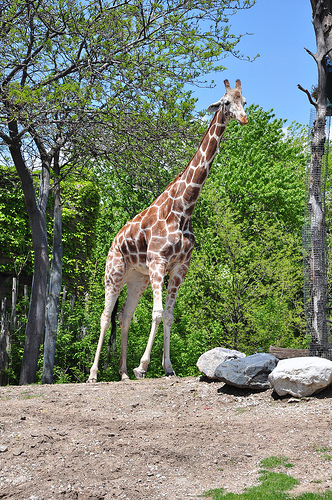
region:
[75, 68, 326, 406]
a giraffe near three stones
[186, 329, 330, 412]
three stones on the ground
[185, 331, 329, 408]
a black stone in the middle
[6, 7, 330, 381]
trees behind a giraffe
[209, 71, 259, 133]
head of giraffe is thin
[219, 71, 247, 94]
horns on head of giraffe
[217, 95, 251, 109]
eyes of giraffe are black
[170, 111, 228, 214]
long neck of giraffe has dark brown spots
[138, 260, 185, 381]
front legs of giraffe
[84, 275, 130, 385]
back legs of giraffe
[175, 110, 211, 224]
giraffe's neck is long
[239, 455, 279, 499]
green patches of grass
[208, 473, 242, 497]
green patches of grass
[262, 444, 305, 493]
green patches of grass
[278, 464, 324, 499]
green patches of grass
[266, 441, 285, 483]
green patches of grass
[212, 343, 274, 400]
the rock is gray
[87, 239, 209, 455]
giraffe's legs are long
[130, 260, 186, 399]
giraffe's legs are long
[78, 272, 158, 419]
giraffe's legs are long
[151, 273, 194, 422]
giraffe's legs are long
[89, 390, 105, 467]
dirt on the ground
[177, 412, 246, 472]
dirt on the ground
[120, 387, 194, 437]
dirt on the ground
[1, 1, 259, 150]
green leaves on tree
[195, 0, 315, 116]
blue of daytime sky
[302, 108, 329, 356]
wire cage on tree trunk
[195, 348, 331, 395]
three rocks on dirt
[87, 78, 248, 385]
giraffe standing on hill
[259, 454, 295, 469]
patch of green grass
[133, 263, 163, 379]
bent leg of giraffe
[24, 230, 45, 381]
shadows on tree trunk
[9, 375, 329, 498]
face of dirt hill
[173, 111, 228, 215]
long neck of giraffe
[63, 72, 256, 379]
giraffe standing beside rocks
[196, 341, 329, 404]
three similar shaped rocks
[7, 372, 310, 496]
dirt giraffe is standing on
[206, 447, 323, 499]
patch of grass in dirt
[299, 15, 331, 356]
tree trunk surrounded by three rocks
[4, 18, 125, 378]
truck on backside of giraffe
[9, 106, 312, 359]
wall of trees behind giraffe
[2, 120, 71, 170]
cloud peaking above the tree tops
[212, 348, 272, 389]
dark rock in between two light rocks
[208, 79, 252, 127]
face of the giraffe